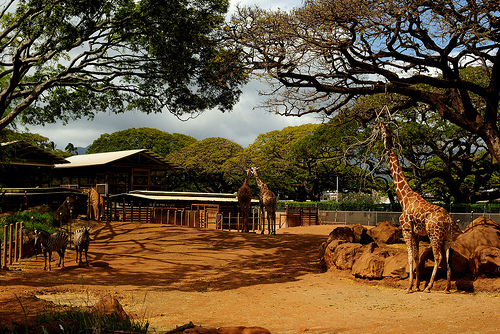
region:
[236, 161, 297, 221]
brown giraffes next to fence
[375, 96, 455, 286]
brown giraffe near rocks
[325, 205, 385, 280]
rocks under a tree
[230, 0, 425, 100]
big brown tree branches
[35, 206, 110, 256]
zebras under a tree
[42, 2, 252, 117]
green tree leaves over zebras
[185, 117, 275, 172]
trees in a wooded area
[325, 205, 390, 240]
rocks near tall giraffe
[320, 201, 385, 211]
fence around zebras and giraffes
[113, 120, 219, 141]
trees in a wood area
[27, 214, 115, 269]
two zebras standing together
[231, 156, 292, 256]
two giraffes standing with each other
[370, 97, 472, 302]
a giraffe eating from tree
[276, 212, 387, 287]
pile of rocks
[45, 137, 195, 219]
roofed building in background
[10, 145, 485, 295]
animals in an enclosure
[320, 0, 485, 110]
tree limbs extended across sky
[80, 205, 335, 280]
shadows cast from trees above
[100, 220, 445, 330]
dirt covered ground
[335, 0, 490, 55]
blue sky behind tree branches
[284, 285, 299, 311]
part of the ground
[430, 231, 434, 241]
body of a giraffe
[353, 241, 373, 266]
edge of a rock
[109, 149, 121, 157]
roof of a building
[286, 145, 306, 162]
leaves of a tree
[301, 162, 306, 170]
branches of a tree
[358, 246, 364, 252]
edge of a rock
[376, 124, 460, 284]
A giraffe standing alone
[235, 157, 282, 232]
a pair of giraffes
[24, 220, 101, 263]
a pair of zebras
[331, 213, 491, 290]
A line of large rocks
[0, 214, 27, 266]
A wooden fence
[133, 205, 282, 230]
A wooden fence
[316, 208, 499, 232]
A chain link fence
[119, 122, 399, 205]
some very large trees in the distance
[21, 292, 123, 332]
some tall grass in the containment area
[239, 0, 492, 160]
a large tree missing several leaves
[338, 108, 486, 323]
the giraffe has tail